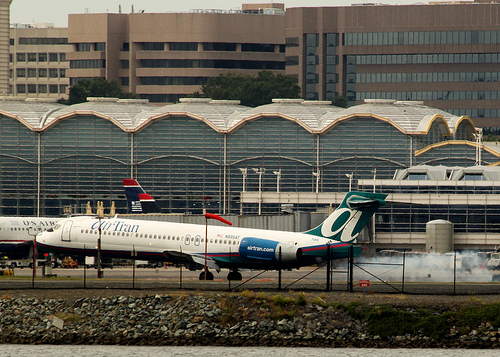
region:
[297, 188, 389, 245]
the airline's logo on the tail of the plane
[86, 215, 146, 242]
the carrier's name is Air Tran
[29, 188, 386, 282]
the Air Train jet is white with blue trim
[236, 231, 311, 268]
this is a two-engine jet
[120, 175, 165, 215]
only the tails of these jets are visible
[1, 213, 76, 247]
a US Air plane behind the AirTran jet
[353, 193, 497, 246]
the terminal has big bay windows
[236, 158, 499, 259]
the airplane terminal behind the AirTran plane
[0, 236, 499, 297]
a chain link fence keeps people off the runways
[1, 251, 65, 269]
a baggage cart at the US Air plane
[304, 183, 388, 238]
a tail of a airplane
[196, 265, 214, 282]
the landing gear of a plane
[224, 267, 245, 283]
the landing gear of a plane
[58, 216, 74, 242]
a door on a plane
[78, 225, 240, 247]
the windows on a plae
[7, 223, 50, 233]
the windows on a plane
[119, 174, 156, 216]
a tail of a plane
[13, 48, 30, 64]
the window of a building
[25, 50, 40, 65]
the window of a building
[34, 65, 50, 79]
the window of a building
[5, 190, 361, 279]
PLANE ON THE RUNWAY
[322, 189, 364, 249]
tail of the plane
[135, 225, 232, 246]
windows on the plane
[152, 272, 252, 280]
wheels of the plane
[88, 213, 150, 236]
logo of the plane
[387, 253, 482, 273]
smoke in the air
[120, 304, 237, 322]
stones on the ground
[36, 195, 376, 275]
A plane sitting on the runway.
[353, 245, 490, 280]
Smoke coming from the plane.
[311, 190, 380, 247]
A big letter "a" on tail of the plane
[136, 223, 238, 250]
The plane has windows.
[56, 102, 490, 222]
The building is part of the airport.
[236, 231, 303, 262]
The engine of the plane.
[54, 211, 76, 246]
The door of the plane.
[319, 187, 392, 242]
Tail of the plane.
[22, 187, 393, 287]
white, blue and green airplane parked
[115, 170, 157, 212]
wings of a plane in the background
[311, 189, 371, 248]
an a written in white on green tail of plane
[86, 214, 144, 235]
airtran written in blue on side of plane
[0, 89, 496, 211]
wide blue building with white roof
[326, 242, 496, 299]
steam coming from back of plane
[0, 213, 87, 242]
plane shows part of brand "us air"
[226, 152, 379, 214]
white poles sticking up on side of building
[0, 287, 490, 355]
rocks on shore of body of water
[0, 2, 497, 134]
tall tan buildings with many windows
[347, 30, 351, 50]
a window on a building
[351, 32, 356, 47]
a window on a building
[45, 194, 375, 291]
A plane on the runway.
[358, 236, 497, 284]
Smoke coming from the plane.